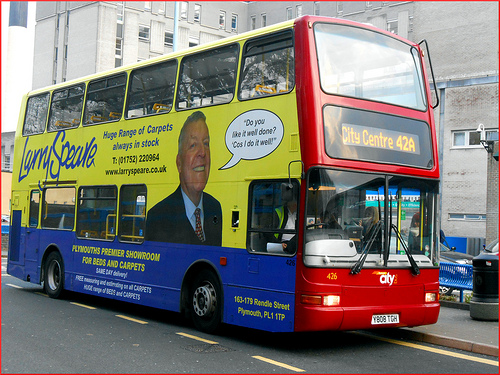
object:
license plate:
[372, 314, 400, 324]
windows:
[239, 30, 292, 98]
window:
[251, 183, 296, 253]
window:
[120, 188, 144, 243]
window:
[40, 184, 73, 227]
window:
[313, 23, 423, 109]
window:
[75, 185, 118, 240]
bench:
[438, 262, 473, 301]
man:
[145, 111, 224, 253]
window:
[177, 44, 235, 109]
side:
[12, 19, 301, 335]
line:
[250, 355, 309, 372]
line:
[176, 332, 219, 345]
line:
[115, 314, 149, 324]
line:
[70, 302, 97, 309]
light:
[324, 295, 340, 305]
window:
[306, 165, 438, 266]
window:
[85, 73, 127, 123]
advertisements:
[18, 110, 299, 248]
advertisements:
[70, 245, 161, 300]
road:
[3, 274, 492, 372]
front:
[307, 15, 436, 328]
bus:
[9, 15, 441, 333]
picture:
[2, 0, 497, 374]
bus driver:
[261, 196, 298, 249]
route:
[342, 126, 416, 151]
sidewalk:
[403, 303, 497, 345]